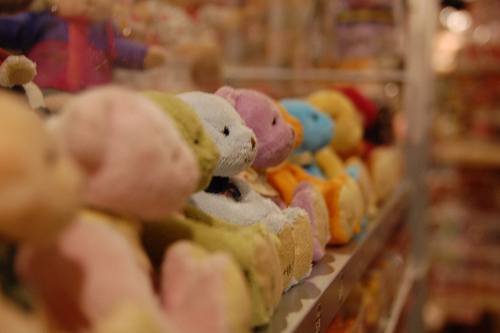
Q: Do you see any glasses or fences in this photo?
A: No, there are no glasses or fences.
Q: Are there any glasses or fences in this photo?
A: No, there are no glasses or fences.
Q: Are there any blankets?
A: No, there are no blankets.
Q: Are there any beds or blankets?
A: No, there are no blankets or beds.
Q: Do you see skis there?
A: No, there are no skis.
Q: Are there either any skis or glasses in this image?
A: No, there are no skis or glasses.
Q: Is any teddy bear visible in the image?
A: Yes, there is a teddy bear.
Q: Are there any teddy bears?
A: Yes, there is a teddy bear.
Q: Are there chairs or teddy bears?
A: Yes, there is a teddy bear.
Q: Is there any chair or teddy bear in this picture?
A: Yes, there is a teddy bear.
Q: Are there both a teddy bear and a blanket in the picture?
A: No, there is a teddy bear but no blankets.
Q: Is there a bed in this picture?
A: No, there are no beds.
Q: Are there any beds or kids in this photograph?
A: No, there are no beds or kids.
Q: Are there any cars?
A: No, there are no cars.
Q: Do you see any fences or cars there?
A: No, there are no cars or fences.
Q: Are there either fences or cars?
A: No, there are no cars or fences.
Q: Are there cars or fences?
A: No, there are no cars or fences.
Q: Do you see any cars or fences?
A: No, there are no cars or fences.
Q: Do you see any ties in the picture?
A: Yes, there is a tie.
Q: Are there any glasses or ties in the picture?
A: Yes, there is a tie.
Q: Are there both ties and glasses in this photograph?
A: No, there is a tie but no glasses.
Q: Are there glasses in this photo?
A: No, there are no glasses.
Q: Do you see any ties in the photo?
A: Yes, there is a tie.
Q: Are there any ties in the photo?
A: Yes, there is a tie.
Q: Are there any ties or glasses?
A: Yes, there is a tie.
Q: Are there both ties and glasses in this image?
A: No, there is a tie but no glasses.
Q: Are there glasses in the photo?
A: No, there are no glasses.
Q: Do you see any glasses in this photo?
A: No, there are no glasses.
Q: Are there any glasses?
A: No, there are no glasses.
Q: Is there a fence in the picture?
A: No, there are no fences.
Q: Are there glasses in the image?
A: No, there are no glasses.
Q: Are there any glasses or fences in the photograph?
A: No, there are no glasses or fences.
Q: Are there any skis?
A: No, there are no skis.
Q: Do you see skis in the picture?
A: No, there are no skis.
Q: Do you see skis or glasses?
A: No, there are no skis or glasses.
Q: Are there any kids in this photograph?
A: No, there are no kids.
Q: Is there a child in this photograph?
A: No, there are no children.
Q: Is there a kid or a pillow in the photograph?
A: No, there are no children or pillows.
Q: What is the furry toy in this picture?
A: The toy is a stuffed animal.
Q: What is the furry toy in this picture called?
A: The toy is a stuffed animal.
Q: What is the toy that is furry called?
A: The toy is a stuffed animal.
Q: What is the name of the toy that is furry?
A: The toy is a stuffed animal.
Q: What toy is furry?
A: The toy is a stuffed animal.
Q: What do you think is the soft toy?
A: The toy is a stuffed animal.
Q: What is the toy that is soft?
A: The toy is a stuffed animal.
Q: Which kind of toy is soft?
A: The toy is a stuffed animal.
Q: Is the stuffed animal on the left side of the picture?
A: Yes, the stuffed animal is on the left of the image.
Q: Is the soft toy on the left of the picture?
A: Yes, the stuffed animal is on the left of the image.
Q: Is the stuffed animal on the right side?
A: No, the stuffed animal is on the left of the image.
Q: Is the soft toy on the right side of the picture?
A: No, the stuffed animal is on the left of the image.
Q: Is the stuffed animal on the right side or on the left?
A: The stuffed animal is on the left of the image.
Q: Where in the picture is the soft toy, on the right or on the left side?
A: The stuffed animal is on the left of the image.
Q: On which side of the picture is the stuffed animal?
A: The stuffed animal is on the left of the image.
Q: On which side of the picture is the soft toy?
A: The stuffed animal is on the left of the image.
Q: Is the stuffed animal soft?
A: Yes, the stuffed animal is soft.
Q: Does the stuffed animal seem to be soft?
A: Yes, the stuffed animal is soft.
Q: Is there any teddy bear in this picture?
A: Yes, there is a teddy bear.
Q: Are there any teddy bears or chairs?
A: Yes, there is a teddy bear.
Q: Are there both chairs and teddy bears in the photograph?
A: No, there is a teddy bear but no chairs.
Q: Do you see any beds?
A: No, there are no beds.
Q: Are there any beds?
A: No, there are no beds.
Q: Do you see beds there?
A: No, there are no beds.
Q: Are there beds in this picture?
A: No, there are no beds.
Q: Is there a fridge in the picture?
A: No, there are no refrigerators.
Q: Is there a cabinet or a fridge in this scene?
A: No, there are no refrigerators or cabinets.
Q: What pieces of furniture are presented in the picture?
A: The pieces of furniture are shelves.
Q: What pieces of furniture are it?
A: The pieces of furniture are shelves.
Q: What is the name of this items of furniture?
A: These are shelves.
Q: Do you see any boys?
A: No, there are no boys.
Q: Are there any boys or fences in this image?
A: No, there are no boys or fences.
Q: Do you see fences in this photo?
A: No, there are no fences.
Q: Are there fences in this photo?
A: No, there are no fences.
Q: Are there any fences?
A: No, there are no fences.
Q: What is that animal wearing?
A: The animal is wearing a jacket.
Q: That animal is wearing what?
A: The animal is wearing a jacket.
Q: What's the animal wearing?
A: The animal is wearing a jacket.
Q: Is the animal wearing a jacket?
A: Yes, the animal is wearing a jacket.